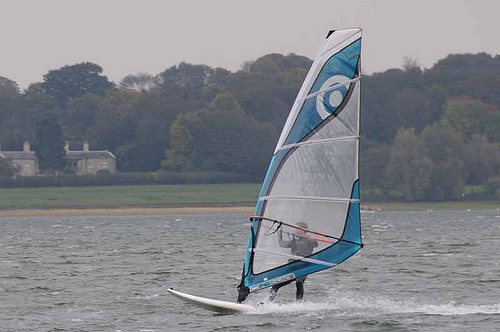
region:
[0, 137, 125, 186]
A house in the distance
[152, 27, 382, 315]
A man participating a water sport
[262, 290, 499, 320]
White foamy water from the watersport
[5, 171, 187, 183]
Green hedges in front of a house in the distance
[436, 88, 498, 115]
Top of a red image through the trees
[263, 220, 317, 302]
Man in the water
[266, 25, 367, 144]
The top of a blue, white and black sail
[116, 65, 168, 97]
A tree without a lot of leaves in the distance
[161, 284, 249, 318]
A white water sport equipment sticking out of the water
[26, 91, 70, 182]
A tall green tree in front of a house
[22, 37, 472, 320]
a man wind surfing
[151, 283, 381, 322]
front half of surfboard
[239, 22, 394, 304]
a blue and white sail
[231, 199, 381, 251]
a black handle bar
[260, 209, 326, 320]
a man in a black wetsuit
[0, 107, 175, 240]
a house by the water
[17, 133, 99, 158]
a few chimneys in a row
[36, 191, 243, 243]
a sandy beach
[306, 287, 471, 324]
a small wake in the water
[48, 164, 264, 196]
a thick hedge wall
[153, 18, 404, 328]
Surfer stand holding a sail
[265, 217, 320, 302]
Surfer wears a suit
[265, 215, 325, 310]
Suit of surfer is black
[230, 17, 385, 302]
Sail of surfboard is white and blue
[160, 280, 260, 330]
Surfboard is white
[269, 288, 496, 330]
Water is choppy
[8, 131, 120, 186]
Buildings on the right side of water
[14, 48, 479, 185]
Trees on the shore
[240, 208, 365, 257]
Surfer holds from stick of sail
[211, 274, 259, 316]
Sail is attached to the surfboard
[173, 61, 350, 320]
a man windsurfing on a calm lake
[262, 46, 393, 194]
a blue and white sail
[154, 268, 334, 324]
a white windsurfing board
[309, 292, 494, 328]
a wake in a lake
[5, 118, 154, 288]
a stone lake house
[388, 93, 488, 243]
trees starting to turn color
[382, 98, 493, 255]
trees along a lake shore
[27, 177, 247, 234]
trimmed green grass on a lake shore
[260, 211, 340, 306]
a man wearing a black wet suit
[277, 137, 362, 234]
transparent sail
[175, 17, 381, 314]
blue and white windsurfer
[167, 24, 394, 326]
man windsurfing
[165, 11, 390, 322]
man in black wet suit windsurfing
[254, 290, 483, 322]
water spray created by windsurfer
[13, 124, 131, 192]
white brick house in distance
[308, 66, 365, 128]
white circle design on windsurf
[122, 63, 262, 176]
large leafy green trees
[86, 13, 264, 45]
grey overcast skies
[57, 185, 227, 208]
well manicured green lawn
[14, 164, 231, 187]
row of green bushes